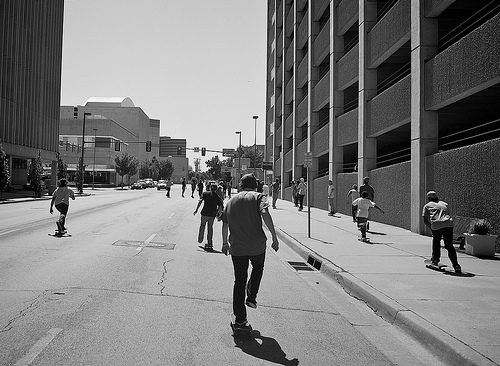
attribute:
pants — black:
[228, 252, 266, 324]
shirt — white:
[348, 196, 379, 220]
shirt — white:
[47, 183, 73, 209]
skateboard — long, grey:
[225, 315, 256, 340]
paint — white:
[12, 324, 67, 364]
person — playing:
[347, 187, 386, 241]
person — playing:
[416, 186, 468, 275]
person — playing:
[218, 172, 284, 335]